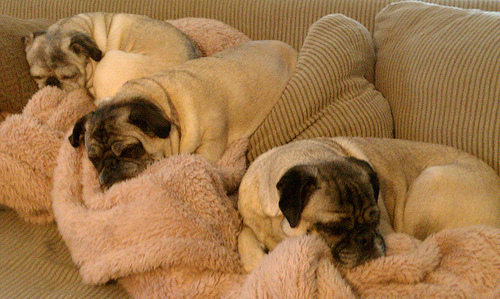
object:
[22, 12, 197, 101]
dog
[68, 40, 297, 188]
dog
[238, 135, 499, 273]
dog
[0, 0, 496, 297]
couch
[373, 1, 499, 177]
pillow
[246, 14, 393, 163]
pillow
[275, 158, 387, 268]
head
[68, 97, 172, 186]
head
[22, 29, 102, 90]
head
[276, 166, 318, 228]
ear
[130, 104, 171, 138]
ear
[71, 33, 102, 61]
ear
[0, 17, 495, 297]
blanket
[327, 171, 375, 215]
forehead